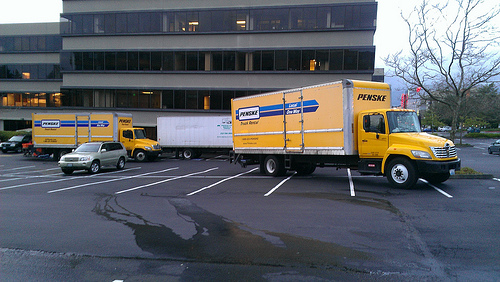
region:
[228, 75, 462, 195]
a yellow penske truck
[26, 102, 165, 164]
a yellow penske truck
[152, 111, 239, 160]
a white semi truck trailer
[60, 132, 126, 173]
a gold ford suv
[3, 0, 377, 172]
a 4 story office building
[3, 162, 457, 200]
white parking space paint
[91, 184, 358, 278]
whet spots on the asphault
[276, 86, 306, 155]
a door to the penske truck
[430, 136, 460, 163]
a silver truck grill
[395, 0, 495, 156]
a barren tree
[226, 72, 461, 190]
the rental truck is yellow with a blue logo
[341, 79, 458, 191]
a logo is above the truck's cab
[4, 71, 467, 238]
the trucks are parked in a building's parking lot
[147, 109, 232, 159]
a white truck is in between the yellow trucks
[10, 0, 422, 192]
the building has lights on in it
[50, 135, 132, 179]
a suv is parked near the trucks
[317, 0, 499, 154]
a bare tree is beside the building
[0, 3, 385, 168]
the building has four stories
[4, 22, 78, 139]
lights are on in the building's second floor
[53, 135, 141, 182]
van is parked in the lot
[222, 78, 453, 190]
yellow moving van parked crooked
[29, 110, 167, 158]
yellow moving van is unloading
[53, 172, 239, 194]
wet lines painted in the parking lot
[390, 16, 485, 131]
bare tree beside the building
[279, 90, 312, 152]
door on the side of the moving truck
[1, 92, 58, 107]
lights on in the building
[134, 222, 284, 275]
pavement is wet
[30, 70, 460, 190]
Two Penske trucks and semi truck are parked in the parking lot.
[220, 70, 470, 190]
Penske truck parked illegally in several parking spaces.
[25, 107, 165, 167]
Second Penske truck not parked in a parking space.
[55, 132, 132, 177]
Small gold SUV parked in the parking lot.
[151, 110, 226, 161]
Semi-truck parked between two yellow Penske trucks.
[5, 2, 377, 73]
Four-story office building is partially occupied.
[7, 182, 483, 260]
The parking lot is near empty.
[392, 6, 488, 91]
A tree without leaves.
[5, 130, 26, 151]
Parked black car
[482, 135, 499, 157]
Dark-colored parked car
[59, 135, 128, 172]
a car in the area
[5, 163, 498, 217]
a parking lot outside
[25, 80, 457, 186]
trucks in the area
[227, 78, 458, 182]
truck is yellow in color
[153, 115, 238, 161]
truck is white in color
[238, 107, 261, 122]
words are on the truck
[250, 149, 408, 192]
wheels on the truck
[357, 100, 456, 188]
the front of the truck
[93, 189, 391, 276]
water on the ground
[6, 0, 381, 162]
a building around the area